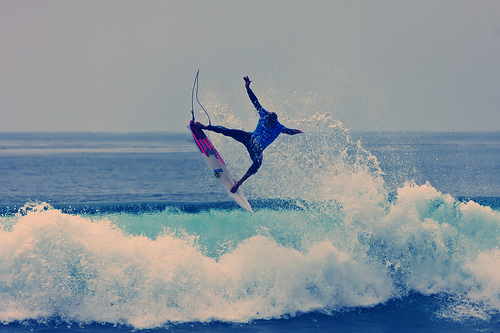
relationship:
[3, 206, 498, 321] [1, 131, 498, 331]
wave breaking in ocean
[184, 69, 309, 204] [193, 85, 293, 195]
surfer in wetsuit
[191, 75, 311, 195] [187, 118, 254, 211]
surfer on board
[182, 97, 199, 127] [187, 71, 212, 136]
piece on end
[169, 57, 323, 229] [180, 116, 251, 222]
man on surfboard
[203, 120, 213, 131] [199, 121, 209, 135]
strap on ankle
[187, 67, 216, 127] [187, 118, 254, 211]
cord connected to board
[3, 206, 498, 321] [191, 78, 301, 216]
wave crashing under surfer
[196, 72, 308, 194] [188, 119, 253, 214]
person on surfboard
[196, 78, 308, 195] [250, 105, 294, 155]
person wearing shirt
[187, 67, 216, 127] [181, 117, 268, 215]
cord connected board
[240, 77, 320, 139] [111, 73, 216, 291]
mans arms in air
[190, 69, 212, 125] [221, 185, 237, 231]
tether from surfers ankle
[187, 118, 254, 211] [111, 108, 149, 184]
board in air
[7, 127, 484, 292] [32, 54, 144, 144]
water splashing air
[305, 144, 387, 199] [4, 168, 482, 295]
splashes coming water